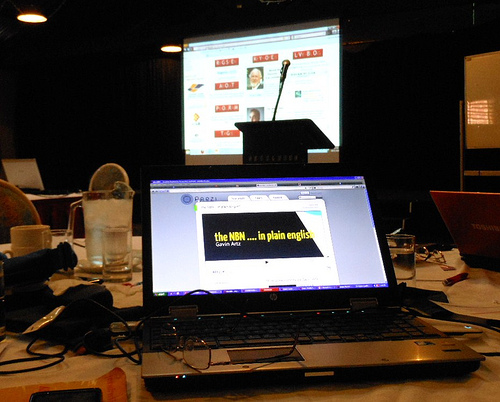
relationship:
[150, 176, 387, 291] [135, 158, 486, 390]
screen on laptop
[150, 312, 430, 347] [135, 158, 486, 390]
keys on laptop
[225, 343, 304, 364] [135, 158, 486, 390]
touchpad on laptop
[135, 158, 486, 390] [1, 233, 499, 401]
laptop on table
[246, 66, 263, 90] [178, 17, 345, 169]
image on projection screen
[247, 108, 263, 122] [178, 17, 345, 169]
man on projection screen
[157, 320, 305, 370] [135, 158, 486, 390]
glasses on laptop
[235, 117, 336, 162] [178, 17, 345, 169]
podium in front of projection screen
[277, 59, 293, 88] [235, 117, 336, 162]
microphone on podium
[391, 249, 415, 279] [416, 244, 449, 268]
water in glasses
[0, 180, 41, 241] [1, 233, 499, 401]
chair at table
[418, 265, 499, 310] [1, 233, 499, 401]
paper on table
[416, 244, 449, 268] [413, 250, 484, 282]
glasses on paper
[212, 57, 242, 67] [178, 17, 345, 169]
symbol on projection screen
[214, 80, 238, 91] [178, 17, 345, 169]
symbol on projection screen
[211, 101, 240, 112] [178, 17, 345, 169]
symbol on projection screen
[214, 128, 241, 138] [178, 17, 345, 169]
symbol on projection screen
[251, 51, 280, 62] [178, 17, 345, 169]
symbol on projection screen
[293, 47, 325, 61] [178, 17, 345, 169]
symbol on projection screen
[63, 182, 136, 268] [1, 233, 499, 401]
water pitcher on table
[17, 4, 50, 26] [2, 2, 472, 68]
light on ceiling